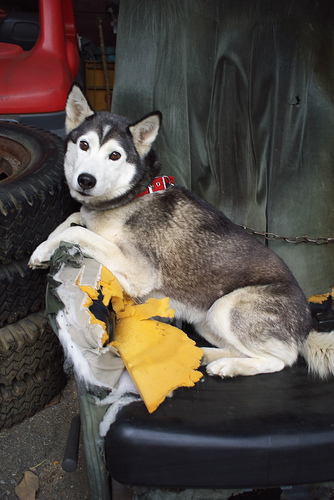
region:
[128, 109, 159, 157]
a dog's left ear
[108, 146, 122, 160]
a dog's left eye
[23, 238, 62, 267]
a dog's left front paw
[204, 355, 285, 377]
a dog's left foot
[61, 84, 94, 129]
a dog's right ear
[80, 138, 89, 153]
a dog's right eye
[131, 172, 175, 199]
a dog's red collar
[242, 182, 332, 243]
a dog's metal chain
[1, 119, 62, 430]
a stack of rubber tires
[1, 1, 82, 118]
a child's toy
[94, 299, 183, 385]
yellow fabric on chair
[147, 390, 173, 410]
frayed edge on yellow fabric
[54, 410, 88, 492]
arm on gray chair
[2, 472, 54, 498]
brown leaf on ground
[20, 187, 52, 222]
black tire on the ground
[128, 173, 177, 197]
red color around dog's neck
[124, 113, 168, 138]
black edge on dog's ear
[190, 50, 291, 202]
odd shape on the wall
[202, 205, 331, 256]
long chain on the wall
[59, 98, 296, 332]
large dog on the seat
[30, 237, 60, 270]
a dog's left paw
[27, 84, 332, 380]
a white and black dog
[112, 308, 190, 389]
The inside of the chair is yellow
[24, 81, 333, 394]
The dog is sitting on the chair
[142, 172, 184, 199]
The dog has a red collar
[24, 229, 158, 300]
The leg of the dog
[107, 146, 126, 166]
The eye of the dog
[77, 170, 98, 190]
The nose of the dog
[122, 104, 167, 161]
The ear of the dog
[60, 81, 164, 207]
The head of the dog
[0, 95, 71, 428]
A stack of tires on the floor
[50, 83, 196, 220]
the head of a dog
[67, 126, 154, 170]
the eyes of a dog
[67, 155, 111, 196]
the nose of a dog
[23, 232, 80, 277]
the paw of a dog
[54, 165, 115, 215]
the mouth of a dog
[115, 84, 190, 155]
the ear of a dog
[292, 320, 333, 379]
the tail of a dog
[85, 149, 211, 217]
a dog wearing a collar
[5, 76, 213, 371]
a dog near a tire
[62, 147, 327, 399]
the body of a dog